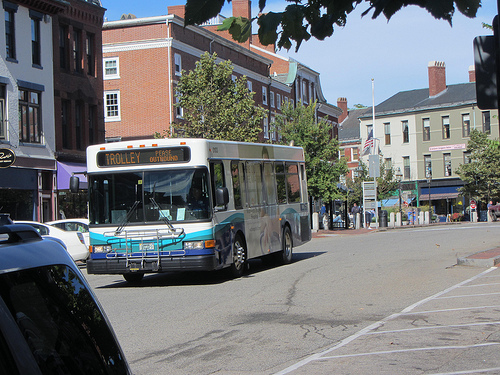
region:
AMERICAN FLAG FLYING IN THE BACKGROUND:
[362, 129, 374, 151]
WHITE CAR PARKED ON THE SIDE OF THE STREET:
[5, 220, 90, 269]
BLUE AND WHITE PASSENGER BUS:
[82, 133, 317, 288]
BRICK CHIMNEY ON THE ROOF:
[427, 60, 448, 101]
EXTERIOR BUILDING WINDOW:
[16, 79, 46, 151]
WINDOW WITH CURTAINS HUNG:
[400, 118, 410, 143]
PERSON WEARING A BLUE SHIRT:
[485, 199, 493, 216]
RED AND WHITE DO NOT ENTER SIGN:
[468, 199, 476, 211]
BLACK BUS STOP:
[325, 181, 350, 231]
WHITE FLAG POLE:
[360, 73, 380, 230]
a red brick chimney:
[424, 49, 456, 106]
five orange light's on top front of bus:
[92, 140, 191, 152]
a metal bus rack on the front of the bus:
[99, 226, 185, 274]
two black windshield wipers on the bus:
[107, 193, 179, 239]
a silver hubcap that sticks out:
[227, 238, 252, 273]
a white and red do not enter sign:
[466, 194, 481, 221]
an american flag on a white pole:
[359, 76, 386, 153]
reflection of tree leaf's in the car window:
[13, 262, 123, 373]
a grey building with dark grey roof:
[365, 62, 498, 204]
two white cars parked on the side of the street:
[5, 209, 100, 262]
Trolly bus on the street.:
[85, 135, 327, 277]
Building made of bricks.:
[111, 23, 176, 131]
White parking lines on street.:
[317, 245, 499, 369]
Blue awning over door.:
[410, 181, 466, 203]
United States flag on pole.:
[360, 123, 380, 154]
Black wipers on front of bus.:
[85, 176, 206, 237]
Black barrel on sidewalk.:
[374, 206, 392, 231]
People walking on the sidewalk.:
[316, 198, 366, 230]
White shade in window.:
[417, 114, 434, 144]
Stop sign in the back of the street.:
[465, 195, 477, 228]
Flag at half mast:
[358, 75, 379, 182]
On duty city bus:
[82, 135, 313, 280]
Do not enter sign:
[467, 192, 477, 222]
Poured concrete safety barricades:
[385, 206, 406, 228]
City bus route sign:
[90, 145, 190, 167]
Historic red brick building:
[121, 10, 182, 135]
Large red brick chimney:
[420, 52, 446, 103]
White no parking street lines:
[380, 261, 453, 371]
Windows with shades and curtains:
[396, 115, 472, 141]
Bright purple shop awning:
[45, 149, 88, 200]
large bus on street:
[83, 137, 315, 279]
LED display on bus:
[97, 146, 189, 167]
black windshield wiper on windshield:
[148, 195, 176, 232]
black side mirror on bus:
[215, 185, 228, 200]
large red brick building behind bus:
[102, 0, 342, 177]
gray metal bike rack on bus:
[103, 225, 183, 272]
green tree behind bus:
[173, 52, 270, 139]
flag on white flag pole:
[366, 72, 375, 154]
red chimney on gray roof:
[428, 65, 447, 96]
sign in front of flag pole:
[361, 182, 379, 227]